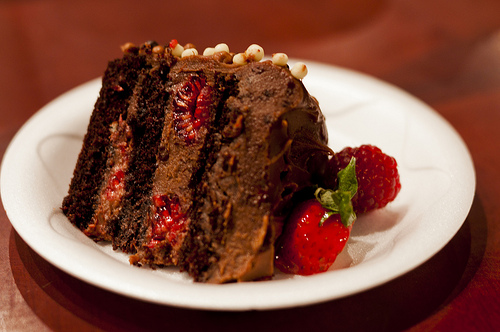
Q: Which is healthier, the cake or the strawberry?
A: The strawberry is healthier than the cake.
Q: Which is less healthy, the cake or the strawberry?
A: The cake is less healthy than the strawberry.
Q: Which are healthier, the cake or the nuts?
A: The nuts are healthier than the cake.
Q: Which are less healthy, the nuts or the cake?
A: The cake are less healthy than the nuts.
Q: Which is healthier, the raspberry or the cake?
A: The raspberry is healthier than the cake.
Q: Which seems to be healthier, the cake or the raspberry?
A: The raspberry is healthier than the cake.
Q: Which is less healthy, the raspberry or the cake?
A: The cake is less healthy than the raspberry.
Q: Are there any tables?
A: Yes, there is a table.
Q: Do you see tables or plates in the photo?
A: Yes, there is a table.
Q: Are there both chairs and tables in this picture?
A: No, there is a table but no chairs.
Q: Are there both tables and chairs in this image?
A: No, there is a table but no chairs.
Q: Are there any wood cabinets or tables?
A: Yes, there is a wood table.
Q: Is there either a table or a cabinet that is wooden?
A: Yes, the table is wooden.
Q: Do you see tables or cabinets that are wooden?
A: Yes, the table is wooden.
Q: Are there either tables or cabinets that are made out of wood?
A: Yes, the table is made of wood.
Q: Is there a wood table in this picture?
A: Yes, there is a table that is made of wood.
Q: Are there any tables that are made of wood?
A: Yes, there is a table that is made of wood.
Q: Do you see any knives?
A: No, there are no knives.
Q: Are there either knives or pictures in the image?
A: No, there are no knives or pictures.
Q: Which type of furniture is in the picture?
A: The furniture is a table.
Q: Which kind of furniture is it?
A: The piece of furniture is a table.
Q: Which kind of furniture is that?
A: This is a table.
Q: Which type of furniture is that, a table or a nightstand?
A: This is a table.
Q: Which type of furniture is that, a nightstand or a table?
A: This is a table.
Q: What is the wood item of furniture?
A: The piece of furniture is a table.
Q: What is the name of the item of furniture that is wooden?
A: The piece of furniture is a table.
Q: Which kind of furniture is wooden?
A: The furniture is a table.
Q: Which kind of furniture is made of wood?
A: The furniture is a table.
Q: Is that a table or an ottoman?
A: That is a table.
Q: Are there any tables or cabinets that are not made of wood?
A: No, there is a table but it is made of wood.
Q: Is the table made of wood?
A: Yes, the table is made of wood.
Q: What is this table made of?
A: The table is made of wood.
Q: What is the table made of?
A: The table is made of wood.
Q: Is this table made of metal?
A: No, the table is made of wood.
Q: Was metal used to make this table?
A: No, the table is made of wood.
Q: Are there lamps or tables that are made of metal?
A: No, there is a table but it is made of wood.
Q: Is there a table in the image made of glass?
A: No, there is a table but it is made of wood.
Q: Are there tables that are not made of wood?
A: No, there is a table but it is made of wood.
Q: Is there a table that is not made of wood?
A: No, there is a table but it is made of wood.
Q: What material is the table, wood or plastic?
A: The table is made of wood.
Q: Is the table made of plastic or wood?
A: The table is made of wood.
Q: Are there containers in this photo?
A: No, there are no containers.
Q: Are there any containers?
A: No, there are no containers.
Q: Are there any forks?
A: No, there are no forks.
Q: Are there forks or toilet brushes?
A: No, there are no forks or toilet brushes.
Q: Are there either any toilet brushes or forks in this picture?
A: No, there are no forks or toilet brushes.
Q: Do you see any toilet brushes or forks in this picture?
A: No, there are no forks or toilet brushes.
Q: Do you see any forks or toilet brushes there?
A: No, there are no forks or toilet brushes.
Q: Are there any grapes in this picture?
A: No, there are no grapes.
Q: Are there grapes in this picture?
A: No, there are no grapes.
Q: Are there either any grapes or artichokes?
A: No, there are no grapes or artichokes.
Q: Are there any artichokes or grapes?
A: No, there are no grapes or artichokes.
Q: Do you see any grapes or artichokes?
A: No, there are no grapes or artichokes.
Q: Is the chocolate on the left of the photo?
A: Yes, the chocolate is on the left of the image.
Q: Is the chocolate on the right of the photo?
A: No, the chocolate is on the left of the image.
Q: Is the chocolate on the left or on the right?
A: The chocolate is on the left of the image.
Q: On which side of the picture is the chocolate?
A: The chocolate is on the left of the image.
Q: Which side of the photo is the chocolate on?
A: The chocolate is on the left of the image.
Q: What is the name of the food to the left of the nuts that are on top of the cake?
A: The food is chocolate.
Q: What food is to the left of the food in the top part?
A: The food is chocolate.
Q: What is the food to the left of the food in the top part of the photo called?
A: The food is chocolate.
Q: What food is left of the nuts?
A: The food is chocolate.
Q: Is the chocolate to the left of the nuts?
A: Yes, the chocolate is to the left of the nuts.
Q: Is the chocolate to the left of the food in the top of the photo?
A: Yes, the chocolate is to the left of the nuts.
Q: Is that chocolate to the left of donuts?
A: No, the chocolate is to the left of the nuts.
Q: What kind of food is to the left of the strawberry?
A: The food is chocolate.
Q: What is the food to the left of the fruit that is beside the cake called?
A: The food is chocolate.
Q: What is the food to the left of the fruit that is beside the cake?
A: The food is chocolate.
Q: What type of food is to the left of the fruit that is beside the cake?
A: The food is chocolate.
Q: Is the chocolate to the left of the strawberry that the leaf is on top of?
A: Yes, the chocolate is to the left of the strawberry.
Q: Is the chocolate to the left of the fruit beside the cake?
A: Yes, the chocolate is to the left of the strawberry.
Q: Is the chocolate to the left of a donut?
A: No, the chocolate is to the left of the strawberry.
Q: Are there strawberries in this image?
A: Yes, there is a strawberry.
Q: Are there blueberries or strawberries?
A: Yes, there is a strawberry.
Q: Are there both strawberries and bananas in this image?
A: No, there is a strawberry but no bananas.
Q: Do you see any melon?
A: No, there are no melons.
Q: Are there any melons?
A: No, there are no melons.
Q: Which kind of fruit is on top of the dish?
A: The fruit is a strawberry.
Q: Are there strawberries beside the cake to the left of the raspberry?
A: Yes, there is a strawberry beside the cake.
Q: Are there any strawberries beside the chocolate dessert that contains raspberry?
A: Yes, there is a strawberry beside the cake.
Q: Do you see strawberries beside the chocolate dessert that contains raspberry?
A: Yes, there is a strawberry beside the cake.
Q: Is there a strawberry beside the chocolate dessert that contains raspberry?
A: Yes, there is a strawberry beside the cake.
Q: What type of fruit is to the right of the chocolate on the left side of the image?
A: The fruit is a strawberry.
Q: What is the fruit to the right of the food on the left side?
A: The fruit is a strawberry.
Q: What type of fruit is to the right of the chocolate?
A: The fruit is a strawberry.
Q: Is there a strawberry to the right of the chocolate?
A: Yes, there is a strawberry to the right of the chocolate.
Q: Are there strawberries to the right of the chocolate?
A: Yes, there is a strawberry to the right of the chocolate.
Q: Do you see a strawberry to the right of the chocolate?
A: Yes, there is a strawberry to the right of the chocolate.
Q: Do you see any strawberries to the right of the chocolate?
A: Yes, there is a strawberry to the right of the chocolate.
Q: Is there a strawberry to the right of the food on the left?
A: Yes, there is a strawberry to the right of the chocolate.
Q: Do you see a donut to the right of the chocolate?
A: No, there is a strawberry to the right of the chocolate.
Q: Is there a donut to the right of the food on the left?
A: No, there is a strawberry to the right of the chocolate.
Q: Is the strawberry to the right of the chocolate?
A: Yes, the strawberry is to the right of the chocolate.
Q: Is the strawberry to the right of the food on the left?
A: Yes, the strawberry is to the right of the chocolate.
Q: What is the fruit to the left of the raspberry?
A: The fruit is a strawberry.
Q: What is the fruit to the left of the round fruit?
A: The fruit is a strawberry.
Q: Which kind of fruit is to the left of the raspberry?
A: The fruit is a strawberry.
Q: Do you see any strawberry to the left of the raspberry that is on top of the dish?
A: Yes, there is a strawberry to the left of the raspberry.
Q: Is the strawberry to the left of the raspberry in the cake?
A: Yes, the strawberry is to the left of the raspberry.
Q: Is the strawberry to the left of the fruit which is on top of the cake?
A: Yes, the strawberry is to the left of the raspberry.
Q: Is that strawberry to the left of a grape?
A: No, the strawberry is to the left of the raspberry.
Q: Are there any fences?
A: No, there are no fences.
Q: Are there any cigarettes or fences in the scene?
A: No, there are no fences or cigarettes.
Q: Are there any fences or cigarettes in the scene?
A: No, there are no fences or cigarettes.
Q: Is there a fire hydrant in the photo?
A: No, there are no fire hydrants.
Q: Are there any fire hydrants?
A: No, there are no fire hydrants.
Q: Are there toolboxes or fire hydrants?
A: No, there are no fire hydrants or toolboxes.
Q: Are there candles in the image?
A: No, there are no candles.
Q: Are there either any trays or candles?
A: No, there are no candles or trays.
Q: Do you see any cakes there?
A: Yes, there is a cake.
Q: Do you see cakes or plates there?
A: Yes, there is a cake.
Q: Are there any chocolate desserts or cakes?
A: Yes, there is a chocolate cake.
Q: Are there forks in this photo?
A: No, there are no forks.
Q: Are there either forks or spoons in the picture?
A: No, there are no forks or spoons.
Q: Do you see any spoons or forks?
A: No, there are no forks or spoons.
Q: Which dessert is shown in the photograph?
A: The dessert is a cake.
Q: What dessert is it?
A: The dessert is a cake.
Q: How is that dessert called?
A: This is a cake.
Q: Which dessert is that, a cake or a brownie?
A: This is a cake.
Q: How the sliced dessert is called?
A: The dessert is a cake.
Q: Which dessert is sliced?
A: The dessert is a cake.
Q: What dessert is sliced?
A: The dessert is a cake.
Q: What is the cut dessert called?
A: The dessert is a cake.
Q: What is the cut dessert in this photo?
A: The dessert is a cake.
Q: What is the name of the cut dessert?
A: The dessert is a cake.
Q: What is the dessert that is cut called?
A: The dessert is a cake.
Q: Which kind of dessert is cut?
A: The dessert is a cake.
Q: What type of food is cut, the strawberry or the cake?
A: The cake is cut.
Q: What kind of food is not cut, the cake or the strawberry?
A: The strawberry is not cut.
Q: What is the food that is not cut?
A: The food is a strawberry.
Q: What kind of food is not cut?
A: The food is a strawberry.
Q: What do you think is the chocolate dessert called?
A: The dessert is a cake.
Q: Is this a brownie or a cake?
A: This is a cake.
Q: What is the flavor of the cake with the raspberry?
A: This is a chocolate cake.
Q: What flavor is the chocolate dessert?
A: This is a chocolate cake.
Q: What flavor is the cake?
A: This is a chocolate cake.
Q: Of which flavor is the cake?
A: This is a chocolate cake.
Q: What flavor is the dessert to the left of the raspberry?
A: This is a chocolate cake.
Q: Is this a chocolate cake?
A: Yes, this is a chocolate cake.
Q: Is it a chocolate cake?
A: Yes, this is a chocolate cake.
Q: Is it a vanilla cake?
A: No, this is a chocolate cake.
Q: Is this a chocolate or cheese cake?
A: This is a chocolate cake.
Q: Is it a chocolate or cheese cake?
A: This is a chocolate cake.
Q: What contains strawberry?
A: The cake contains strawberry.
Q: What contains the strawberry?
A: The cake contains strawberry.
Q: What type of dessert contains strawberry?
A: The dessert is a cake.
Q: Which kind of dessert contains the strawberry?
A: The dessert is a cake.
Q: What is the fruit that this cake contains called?
A: The fruit is a strawberry.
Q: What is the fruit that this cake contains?
A: The fruit is a strawberry.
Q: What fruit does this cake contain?
A: The cake contains strawberry.